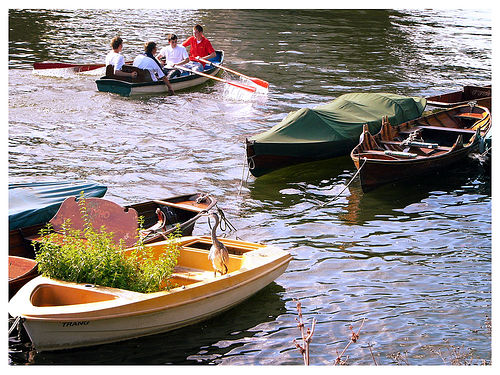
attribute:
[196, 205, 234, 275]
heron — gray and white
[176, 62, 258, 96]
oar — long, red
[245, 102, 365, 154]
boat — green, covered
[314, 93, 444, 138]
cover — green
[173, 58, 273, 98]
paddle — brown, red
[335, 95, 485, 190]
boat — brown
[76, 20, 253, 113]
boat — row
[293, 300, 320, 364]
branch — brown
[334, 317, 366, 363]
branch — brown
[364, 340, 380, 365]
branch — brown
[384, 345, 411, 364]
branch — brown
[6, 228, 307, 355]
boat — small, beige, white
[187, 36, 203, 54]
shirt — red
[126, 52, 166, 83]
shirt — white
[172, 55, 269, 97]
wood oars — long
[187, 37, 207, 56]
shirt — red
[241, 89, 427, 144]
cover — green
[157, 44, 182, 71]
shirt — white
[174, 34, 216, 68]
shirt — red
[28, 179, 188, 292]
plants — green